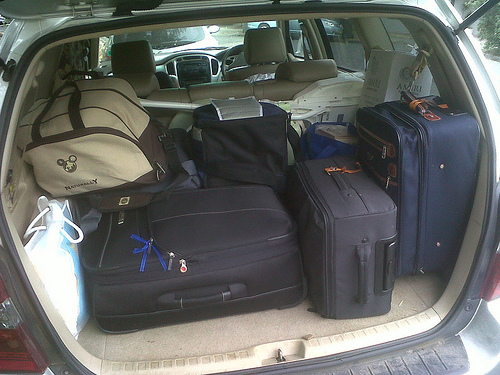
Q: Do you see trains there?
A: No, there are no trains.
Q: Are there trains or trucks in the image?
A: No, there are no trains or trucks.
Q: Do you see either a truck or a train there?
A: No, there are no trains or trucks.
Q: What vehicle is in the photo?
A: The vehicle is a car.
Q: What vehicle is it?
A: The vehicle is a car.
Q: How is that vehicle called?
A: This is a car.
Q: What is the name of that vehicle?
A: This is a car.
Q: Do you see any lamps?
A: No, there are no lamps.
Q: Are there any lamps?
A: No, there are no lamps.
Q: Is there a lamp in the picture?
A: No, there are no lamps.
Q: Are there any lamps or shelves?
A: No, there are no lamps or shelves.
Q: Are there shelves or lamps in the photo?
A: No, there are no lamps or shelves.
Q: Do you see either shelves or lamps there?
A: No, there are no lamps or shelves.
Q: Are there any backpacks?
A: Yes, there is a backpack.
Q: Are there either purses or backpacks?
A: Yes, there is a backpack.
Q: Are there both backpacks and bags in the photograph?
A: Yes, there are both a backpack and a bag.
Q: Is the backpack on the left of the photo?
A: Yes, the backpack is on the left of the image.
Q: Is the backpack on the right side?
A: No, the backpack is on the left of the image.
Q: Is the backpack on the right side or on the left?
A: The backpack is on the left of the image.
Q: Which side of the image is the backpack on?
A: The backpack is on the left of the image.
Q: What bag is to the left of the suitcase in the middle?
A: The bag is a backpack.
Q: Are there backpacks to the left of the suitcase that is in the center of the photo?
A: Yes, there is a backpack to the left of the suitcase.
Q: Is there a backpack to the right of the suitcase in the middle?
A: No, the backpack is to the left of the suitcase.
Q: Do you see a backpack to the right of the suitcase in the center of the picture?
A: No, the backpack is to the left of the suitcase.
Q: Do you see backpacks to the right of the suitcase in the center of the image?
A: No, the backpack is to the left of the suitcase.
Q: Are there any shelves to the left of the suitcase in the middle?
A: No, there is a backpack to the left of the suitcase.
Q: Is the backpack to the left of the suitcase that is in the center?
A: Yes, the backpack is to the left of the suitcase.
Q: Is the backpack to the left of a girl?
A: No, the backpack is to the left of the suitcase.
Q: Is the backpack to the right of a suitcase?
A: No, the backpack is to the left of a suitcase.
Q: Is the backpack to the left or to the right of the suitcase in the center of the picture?
A: The backpack is to the left of the suitcase.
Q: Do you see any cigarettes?
A: No, there are no cigarettes.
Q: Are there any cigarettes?
A: No, there are no cigarettes.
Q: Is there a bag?
A: Yes, there is a bag.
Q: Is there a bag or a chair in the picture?
A: Yes, there is a bag.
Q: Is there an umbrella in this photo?
A: No, there are no umbrellas.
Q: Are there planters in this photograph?
A: No, there are no planters.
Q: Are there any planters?
A: No, there are no planters.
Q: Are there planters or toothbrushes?
A: No, there are no planters or toothbrushes.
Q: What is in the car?
A: The luggage is in the car.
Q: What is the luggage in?
A: The luggage is in the car.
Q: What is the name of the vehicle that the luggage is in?
A: The vehicle is a car.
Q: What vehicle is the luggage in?
A: The luggage is in the car.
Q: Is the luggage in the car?
A: Yes, the luggage is in the car.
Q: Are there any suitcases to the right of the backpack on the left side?
A: Yes, there is a suitcase to the right of the backpack.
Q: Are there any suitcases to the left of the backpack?
A: No, the suitcase is to the right of the backpack.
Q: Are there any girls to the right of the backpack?
A: No, there is a suitcase to the right of the backpack.